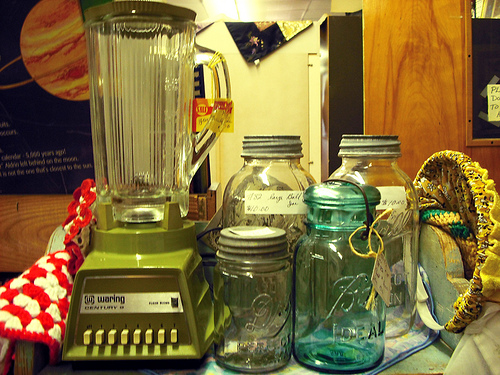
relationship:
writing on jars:
[312, 270, 383, 321] [208, 142, 438, 372]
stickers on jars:
[250, 179, 309, 221] [208, 142, 438, 372]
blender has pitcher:
[36, 1, 241, 373] [46, 3, 199, 234]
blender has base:
[36, 1, 241, 373] [67, 169, 230, 360]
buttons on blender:
[80, 326, 179, 352] [36, 1, 241, 373]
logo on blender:
[81, 285, 128, 315] [36, 1, 241, 373]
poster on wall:
[3, 2, 212, 188] [213, 32, 301, 168]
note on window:
[483, 81, 499, 130] [457, 1, 496, 143]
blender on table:
[36, 1, 241, 373] [48, 354, 499, 375]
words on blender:
[143, 70, 185, 94] [36, 1, 241, 373]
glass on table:
[187, 132, 424, 346] [48, 354, 499, 375]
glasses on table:
[233, 109, 424, 328] [48, 354, 499, 375]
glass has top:
[187, 132, 424, 346] [241, 134, 311, 160]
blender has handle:
[36, 1, 241, 373] [186, 28, 244, 175]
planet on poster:
[24, 8, 90, 107] [3, 2, 212, 188]